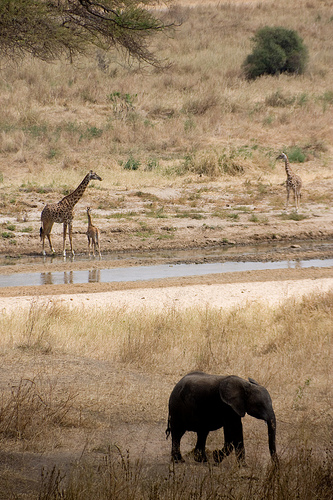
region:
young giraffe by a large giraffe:
[86, 207, 101, 258]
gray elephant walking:
[165, 372, 280, 467]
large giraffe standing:
[39, 170, 102, 257]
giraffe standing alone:
[276, 153, 302, 212]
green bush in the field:
[245, 26, 304, 77]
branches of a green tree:
[0, 0, 182, 71]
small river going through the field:
[0, 258, 332, 287]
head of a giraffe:
[87, 170, 104, 180]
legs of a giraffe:
[41, 221, 76, 257]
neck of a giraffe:
[284, 160, 292, 178]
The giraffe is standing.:
[28, 160, 109, 258]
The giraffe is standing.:
[78, 200, 129, 263]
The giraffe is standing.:
[242, 133, 312, 236]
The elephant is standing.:
[136, 346, 302, 480]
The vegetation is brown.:
[0, 284, 332, 499]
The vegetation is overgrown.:
[0, 282, 332, 498]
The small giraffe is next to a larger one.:
[26, 154, 117, 263]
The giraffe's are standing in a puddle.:
[1, 159, 126, 287]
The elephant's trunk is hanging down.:
[149, 356, 293, 485]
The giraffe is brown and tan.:
[29, 162, 105, 261]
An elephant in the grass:
[166, 371, 279, 466]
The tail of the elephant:
[165, 398, 173, 437]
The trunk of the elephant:
[266, 418, 279, 466]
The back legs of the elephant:
[171, 428, 207, 461]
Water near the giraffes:
[0, 257, 330, 288]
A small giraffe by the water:
[86, 208, 102, 256]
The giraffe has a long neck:
[63, 178, 89, 204]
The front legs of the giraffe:
[61, 217, 74, 258]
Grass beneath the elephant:
[1, 311, 331, 497]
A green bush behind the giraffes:
[243, 28, 307, 77]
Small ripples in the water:
[15, 272, 31, 281]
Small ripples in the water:
[42, 270, 70, 286]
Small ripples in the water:
[78, 270, 105, 278]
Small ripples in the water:
[115, 265, 154, 280]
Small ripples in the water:
[170, 261, 206, 272]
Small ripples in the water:
[211, 257, 254, 274]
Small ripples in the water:
[273, 258, 330, 263]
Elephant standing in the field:
[157, 347, 278, 490]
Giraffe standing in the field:
[26, 132, 95, 283]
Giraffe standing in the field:
[81, 206, 104, 260]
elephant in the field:
[160, 365, 285, 474]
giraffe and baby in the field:
[32, 166, 110, 265]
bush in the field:
[233, 23, 317, 86]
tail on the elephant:
[160, 417, 172, 443]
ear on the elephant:
[215, 372, 242, 416]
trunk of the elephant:
[259, 419, 281, 464]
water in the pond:
[61, 267, 149, 281]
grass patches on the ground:
[127, 226, 181, 245]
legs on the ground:
[162, 438, 253, 470]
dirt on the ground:
[105, 427, 143, 439]